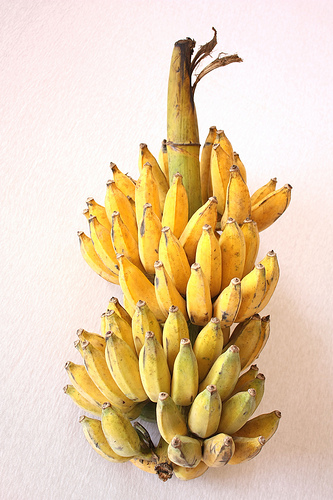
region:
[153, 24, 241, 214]
A tree branch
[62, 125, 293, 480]
A bushel of bananas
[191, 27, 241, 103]
A portion of the branch peeling off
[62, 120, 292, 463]
some bananas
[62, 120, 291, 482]
some bananas on a branch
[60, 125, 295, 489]
some fresh bananas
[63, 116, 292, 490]
a lot of bananas on a branch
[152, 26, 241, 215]
the branch of a tree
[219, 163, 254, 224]
A banana on a branch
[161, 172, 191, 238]
A banana on a branch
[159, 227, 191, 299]
Large yellow is banana pointing up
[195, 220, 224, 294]
Large yellow is banana pointing up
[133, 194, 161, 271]
Large yellow is banana pointing up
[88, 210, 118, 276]
Large yellow is banana pointing up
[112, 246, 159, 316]
Large yellow is banana pointing up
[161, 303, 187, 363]
Large yellow banana next to large yellow banana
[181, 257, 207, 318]
Large yellow banana next to large yellow banana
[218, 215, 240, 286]
Large yellow banana next to large yellow banana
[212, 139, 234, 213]
Large yellow banana next to large yellow banana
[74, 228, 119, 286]
Large yellow banana next to large yellow banana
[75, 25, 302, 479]
Plantains hanging around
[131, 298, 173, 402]
Plantain under a plantain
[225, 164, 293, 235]
plantain to the right of a plantain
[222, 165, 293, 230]
plantain to the left of a plantain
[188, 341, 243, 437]
plantain above a plantain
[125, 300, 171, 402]
plantain above a plantain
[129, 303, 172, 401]
plantain below a plantain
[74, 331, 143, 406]
plantain to the left of a plantain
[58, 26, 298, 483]
plantain waiting to be eaten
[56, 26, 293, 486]
plantains waiting to ripen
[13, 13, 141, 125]
The wall is white.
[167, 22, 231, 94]
The stem is broken.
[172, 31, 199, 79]
The stem is black.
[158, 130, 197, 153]
Black ring around the stem.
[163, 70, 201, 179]
The stem is greenish brown.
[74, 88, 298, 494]
Bananas are upside down.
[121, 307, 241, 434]
The bananas are yellow.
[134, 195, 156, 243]
Black on the banana.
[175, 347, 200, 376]
Green on the banana.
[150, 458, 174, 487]
Small part of the stem.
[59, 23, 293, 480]
display of bunches of bananas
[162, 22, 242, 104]
dried and hanging pieces of banana stem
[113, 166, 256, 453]
bottoms of bananas pointing upward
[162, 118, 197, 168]
horizontal brown line on banana stem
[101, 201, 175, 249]
dark gray lines on ends of bananas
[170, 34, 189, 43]
blackened cut of banana stem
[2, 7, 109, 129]
textured white surface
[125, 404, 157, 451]
space between bananas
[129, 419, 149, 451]
dark and dried banana peel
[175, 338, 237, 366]
green edges of banana peels